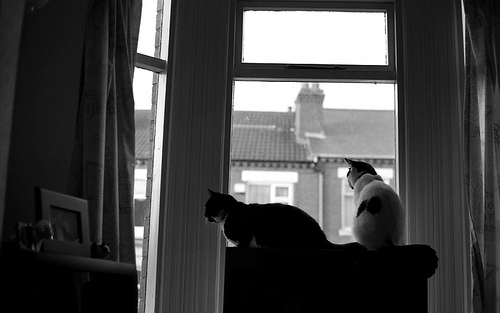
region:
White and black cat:
[336, 148, 409, 258]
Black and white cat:
[201, 194, 323, 247]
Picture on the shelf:
[42, 191, 92, 255]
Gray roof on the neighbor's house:
[248, 140, 273, 157]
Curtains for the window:
[88, 47, 133, 202]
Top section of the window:
[229, 75, 396, 152]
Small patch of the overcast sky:
[293, 25, 340, 57]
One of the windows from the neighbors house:
[248, 180, 273, 202]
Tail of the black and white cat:
[333, 237, 364, 254]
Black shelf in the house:
[34, 261, 129, 311]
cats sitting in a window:
[204, 161, 416, 250]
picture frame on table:
[37, 193, 103, 251]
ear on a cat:
[202, 177, 223, 199]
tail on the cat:
[331, 230, 366, 259]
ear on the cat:
[342, 157, 356, 169]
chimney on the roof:
[290, 86, 345, 143]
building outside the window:
[239, 100, 386, 175]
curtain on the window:
[10, 43, 151, 196]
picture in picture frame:
[56, 207, 85, 236]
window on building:
[250, 169, 299, 201]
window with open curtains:
[239, 78, 391, 145]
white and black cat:
[345, 147, 414, 276]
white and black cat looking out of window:
[329, 116, 416, 266]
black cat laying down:
[195, 179, 368, 263]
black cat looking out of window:
[194, 184, 366, 273]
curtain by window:
[62, 13, 139, 173]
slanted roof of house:
[247, 109, 316, 158]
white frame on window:
[242, 167, 299, 198]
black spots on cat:
[353, 191, 391, 223]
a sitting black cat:
[195, 186, 362, 251]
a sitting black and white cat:
[330, 154, 402, 254]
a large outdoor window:
[225, 4, 410, 251]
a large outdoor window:
[133, 0, 155, 308]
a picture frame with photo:
[38, 184, 92, 254]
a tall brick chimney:
[292, 80, 332, 148]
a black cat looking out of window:
[196, 184, 363, 256]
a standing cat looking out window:
[340, 154, 415, 259]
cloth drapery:
[33, 2, 141, 250]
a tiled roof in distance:
[233, 109, 388, 165]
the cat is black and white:
[343, 168, 407, 241]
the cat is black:
[203, 195, 312, 245]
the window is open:
[233, 12, 414, 168]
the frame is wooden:
[38, 192, 105, 262]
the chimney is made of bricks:
[296, 88, 337, 123]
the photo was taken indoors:
[8, 8, 498, 308]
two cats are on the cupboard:
[183, 141, 425, 260]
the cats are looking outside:
[192, 148, 408, 250]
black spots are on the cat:
[353, 200, 385, 212]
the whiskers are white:
[206, 218, 226, 234]